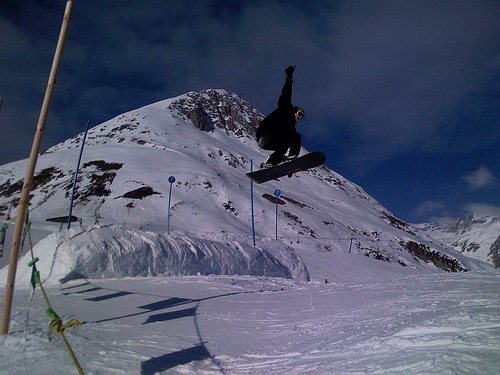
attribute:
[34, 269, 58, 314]
rope — tied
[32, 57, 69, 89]
pole — tall, blue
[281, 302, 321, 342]
snow — drift, white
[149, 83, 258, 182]
mountain — covered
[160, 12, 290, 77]
sky — cloudy, blue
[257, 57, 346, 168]
snowboarder — airborn, tricking, wearing